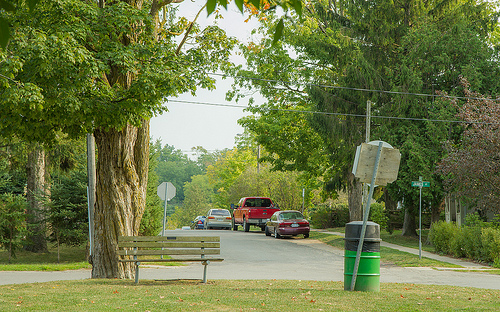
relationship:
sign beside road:
[408, 179, 432, 188] [1, 227, 499, 290]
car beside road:
[264, 210, 313, 242] [1, 227, 499, 290]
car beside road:
[230, 196, 280, 232] [1, 227, 499, 290]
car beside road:
[206, 208, 234, 230] [1, 227, 499, 290]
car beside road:
[191, 213, 207, 230] [1, 227, 499, 290]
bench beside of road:
[117, 235, 223, 283] [1, 227, 499, 290]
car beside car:
[264, 210, 313, 242] [230, 196, 280, 232]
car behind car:
[230, 196, 280, 232] [206, 208, 234, 230]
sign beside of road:
[408, 179, 432, 188] [1, 227, 499, 290]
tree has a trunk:
[432, 73, 499, 215] [92, 129, 154, 284]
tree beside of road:
[432, 73, 499, 215] [1, 227, 499, 290]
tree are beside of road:
[432, 73, 499, 215] [1, 227, 499, 290]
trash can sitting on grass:
[344, 219, 383, 293] [2, 279, 499, 310]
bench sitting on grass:
[117, 235, 223, 283] [2, 279, 499, 310]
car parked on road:
[264, 210, 313, 242] [1, 227, 499, 290]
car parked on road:
[206, 208, 234, 230] [1, 227, 499, 290]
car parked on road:
[191, 213, 207, 230] [1, 227, 499, 290]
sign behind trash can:
[347, 138, 401, 292] [344, 219, 383, 293]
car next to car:
[230, 196, 280, 232] [264, 210, 313, 242]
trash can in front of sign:
[344, 219, 383, 293] [347, 138, 401, 292]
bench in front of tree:
[117, 235, 223, 283] [432, 73, 499, 215]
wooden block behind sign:
[354, 142, 401, 189] [347, 138, 401, 292]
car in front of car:
[230, 196, 280, 232] [264, 210, 313, 242]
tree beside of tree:
[432, 73, 499, 224] [432, 73, 499, 215]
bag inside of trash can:
[343, 239, 380, 254] [344, 219, 383, 293]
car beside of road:
[230, 196, 280, 232] [1, 227, 499, 290]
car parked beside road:
[264, 210, 313, 242] [1, 227, 499, 290]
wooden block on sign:
[354, 142, 401, 189] [347, 138, 401, 292]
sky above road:
[144, 3, 321, 165] [1, 227, 499, 290]